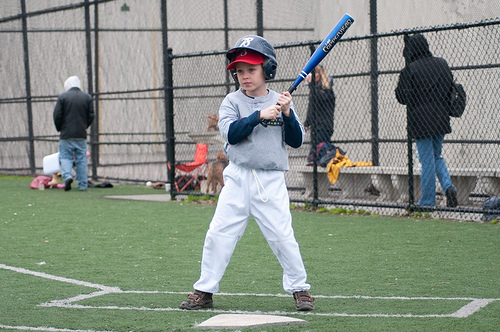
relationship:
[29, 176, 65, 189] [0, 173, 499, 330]
child on field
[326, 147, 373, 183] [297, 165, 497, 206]
jacket on bench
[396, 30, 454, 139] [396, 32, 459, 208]
jacket on a person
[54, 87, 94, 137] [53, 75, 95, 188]
jacket on a person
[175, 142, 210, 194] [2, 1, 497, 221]
seat near fence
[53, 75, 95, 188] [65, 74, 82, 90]
man has a hood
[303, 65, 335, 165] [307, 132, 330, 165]
woman has jeans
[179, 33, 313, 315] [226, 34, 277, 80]
kid wearing helmet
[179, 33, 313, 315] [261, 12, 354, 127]
kid holds baseball bat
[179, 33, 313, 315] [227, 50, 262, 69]
kid wearing baseball hat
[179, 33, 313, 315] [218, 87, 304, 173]
kid wearing shirt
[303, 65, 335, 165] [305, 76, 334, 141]
woman wearing a coat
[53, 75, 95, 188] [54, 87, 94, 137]
person wearing a coat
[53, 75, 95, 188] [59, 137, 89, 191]
person wearing jeans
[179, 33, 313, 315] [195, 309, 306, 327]
kid standing at home base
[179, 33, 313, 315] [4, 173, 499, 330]
kid on field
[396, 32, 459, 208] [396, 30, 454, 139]
person wearing jacket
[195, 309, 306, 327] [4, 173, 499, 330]
home base on field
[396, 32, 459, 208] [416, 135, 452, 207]
person wearing jeans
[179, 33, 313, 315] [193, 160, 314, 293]
kid wearing pants